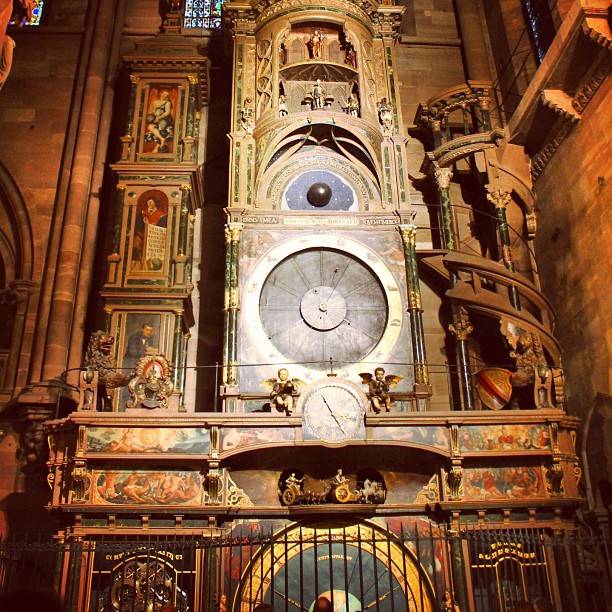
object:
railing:
[0, 522, 610, 612]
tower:
[219, 0, 433, 414]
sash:
[476, 368, 512, 410]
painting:
[131, 189, 169, 273]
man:
[133, 197, 167, 262]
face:
[259, 247, 388, 371]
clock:
[241, 233, 404, 386]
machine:
[103, 554, 180, 612]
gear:
[132, 561, 162, 579]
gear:
[126, 562, 147, 583]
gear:
[146, 586, 177, 609]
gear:
[111, 583, 139, 610]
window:
[184, 0, 223, 30]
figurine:
[345, 45, 357, 68]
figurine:
[306, 29, 323, 59]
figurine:
[278, 39, 287, 68]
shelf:
[278, 57, 358, 82]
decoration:
[282, 469, 350, 505]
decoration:
[331, 469, 386, 504]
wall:
[0, 0, 612, 608]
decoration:
[358, 367, 403, 414]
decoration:
[259, 369, 307, 417]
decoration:
[509, 332, 547, 387]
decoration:
[126, 354, 174, 410]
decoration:
[84, 330, 135, 413]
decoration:
[434, 168, 454, 250]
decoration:
[116, 185, 182, 286]